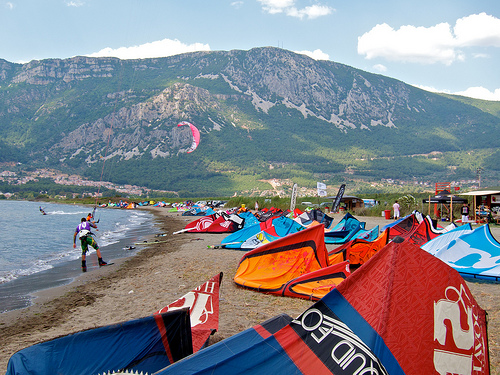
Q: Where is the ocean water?
A: On the left side of the photo.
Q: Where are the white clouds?
A: Above the mountain.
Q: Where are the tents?
A: On the beach.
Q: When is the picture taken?
A: Daytime.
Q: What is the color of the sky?
A: Blue.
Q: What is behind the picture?
A: Mountain.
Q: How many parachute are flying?
A: One.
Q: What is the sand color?
A: Brown.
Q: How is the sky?
A: Cloudy.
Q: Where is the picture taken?
A: At a popular kite surf beach.